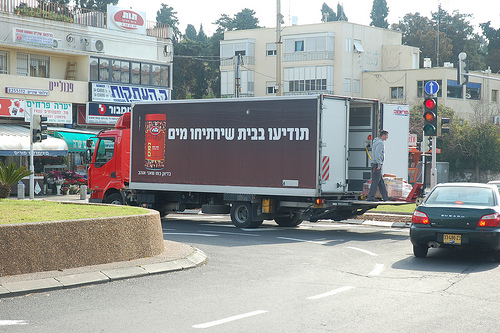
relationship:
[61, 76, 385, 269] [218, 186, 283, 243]
truck on tires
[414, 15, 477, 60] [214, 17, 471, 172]
trees behind buildings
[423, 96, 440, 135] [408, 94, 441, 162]
lights are traffic lights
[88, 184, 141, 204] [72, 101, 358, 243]
wheels of a truck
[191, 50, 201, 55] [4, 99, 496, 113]
trees are in distance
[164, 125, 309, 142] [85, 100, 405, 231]
writing on side of truck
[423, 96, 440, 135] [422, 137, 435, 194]
lights on post